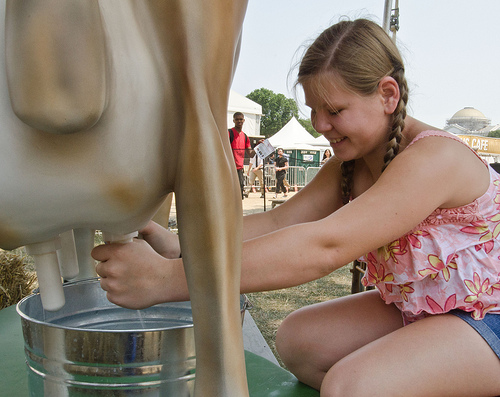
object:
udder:
[30, 242, 65, 310]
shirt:
[356, 132, 499, 321]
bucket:
[16, 277, 248, 397]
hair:
[291, 18, 408, 292]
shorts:
[452, 310, 500, 365]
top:
[228, 127, 249, 168]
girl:
[90, 14, 498, 394]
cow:
[3, 1, 249, 396]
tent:
[261, 116, 317, 148]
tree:
[244, 89, 295, 142]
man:
[228, 111, 264, 199]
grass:
[243, 254, 354, 357]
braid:
[382, 67, 408, 169]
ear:
[379, 77, 400, 115]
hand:
[90, 239, 170, 311]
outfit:
[273, 157, 288, 192]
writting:
[470, 139, 489, 152]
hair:
[233, 112, 242, 118]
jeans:
[451, 310, 500, 356]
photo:
[0, 0, 499, 396]